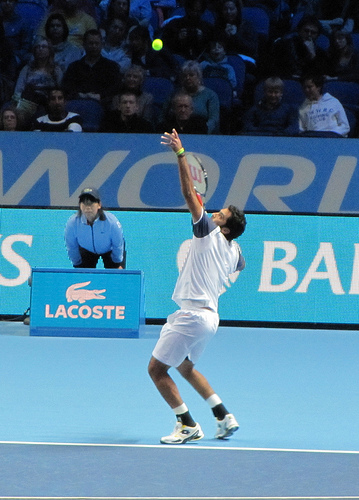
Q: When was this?
A: Daytime.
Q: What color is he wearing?
A: White.